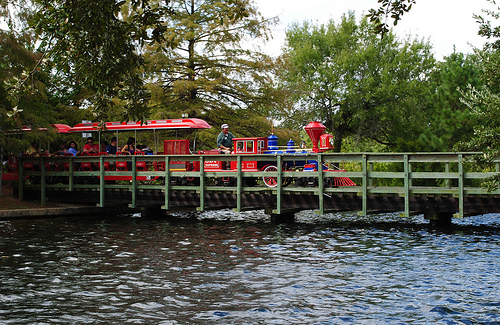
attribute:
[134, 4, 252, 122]
trees — brown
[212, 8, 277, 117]
leaves — green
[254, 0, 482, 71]
sky — sunlit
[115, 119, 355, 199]
train — red 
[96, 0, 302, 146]
tree — yellow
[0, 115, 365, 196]
train — red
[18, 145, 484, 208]
track — above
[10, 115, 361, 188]
train — mini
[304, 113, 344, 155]
cowcatcher — Bright red 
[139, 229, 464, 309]
water — rippling surface 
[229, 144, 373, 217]
bridge — wooden